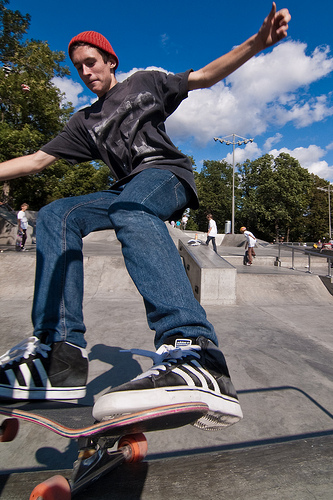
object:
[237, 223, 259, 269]
boy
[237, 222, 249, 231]
helmet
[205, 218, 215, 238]
white t-shirt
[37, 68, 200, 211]
tee shirt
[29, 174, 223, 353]
jeans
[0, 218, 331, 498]
park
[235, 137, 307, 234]
trees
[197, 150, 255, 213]
trees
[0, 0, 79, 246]
trees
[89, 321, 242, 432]
sneakers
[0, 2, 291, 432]
boy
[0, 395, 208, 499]
skateboard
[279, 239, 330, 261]
metal rail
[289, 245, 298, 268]
pole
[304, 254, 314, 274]
pole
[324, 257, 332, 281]
pole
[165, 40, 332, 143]
cloud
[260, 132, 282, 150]
cloud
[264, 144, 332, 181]
cloud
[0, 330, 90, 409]
sneakers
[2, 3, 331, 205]
sky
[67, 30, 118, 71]
hat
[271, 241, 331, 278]
rail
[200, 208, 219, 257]
young men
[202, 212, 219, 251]
man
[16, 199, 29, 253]
man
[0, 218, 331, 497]
skatepark